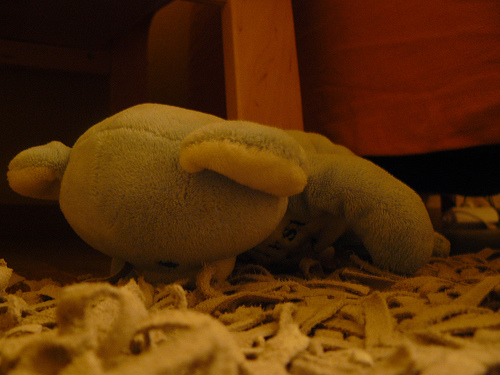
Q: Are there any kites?
A: No, there are no kites.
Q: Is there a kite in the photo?
A: No, there are no kites.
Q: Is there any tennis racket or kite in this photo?
A: No, there are no kites or rackets.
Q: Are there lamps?
A: No, there are no lamps.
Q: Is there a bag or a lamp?
A: No, there are no lamps or bags.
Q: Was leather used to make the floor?
A: Yes, the floor is made of leather.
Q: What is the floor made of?
A: The floor is made of leather.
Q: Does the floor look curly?
A: Yes, the floor is curly.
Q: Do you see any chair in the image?
A: Yes, there is a chair.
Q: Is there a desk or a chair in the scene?
A: Yes, there is a chair.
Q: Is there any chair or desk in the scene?
A: Yes, there is a chair.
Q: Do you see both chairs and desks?
A: No, there is a chair but no desks.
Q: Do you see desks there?
A: No, there are no desks.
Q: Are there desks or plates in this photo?
A: No, there are no desks or plates.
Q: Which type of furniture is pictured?
A: The furniture is a chair.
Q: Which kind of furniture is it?
A: The piece of furniture is a chair.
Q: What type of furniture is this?
A: This is a chair.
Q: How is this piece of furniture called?
A: This is a chair.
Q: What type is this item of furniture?
A: This is a chair.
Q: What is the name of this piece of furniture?
A: This is a chair.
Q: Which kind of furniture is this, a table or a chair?
A: This is a chair.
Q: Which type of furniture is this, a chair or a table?
A: This is a chair.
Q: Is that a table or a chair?
A: That is a chair.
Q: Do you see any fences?
A: No, there are no fences.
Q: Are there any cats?
A: No, there are no cats.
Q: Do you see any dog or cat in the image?
A: No, there are no cats or dogs.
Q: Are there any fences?
A: No, there are no fences.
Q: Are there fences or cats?
A: No, there are no fences or cats.